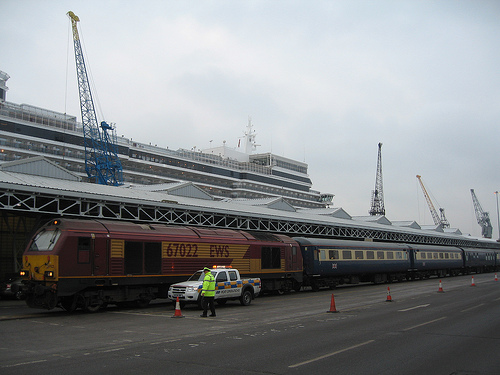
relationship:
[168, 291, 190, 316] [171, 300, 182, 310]
cone has stripe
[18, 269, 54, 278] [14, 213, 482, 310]
headlights on train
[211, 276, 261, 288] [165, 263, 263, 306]
checkers on truck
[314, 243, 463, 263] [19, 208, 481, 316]
stripe on train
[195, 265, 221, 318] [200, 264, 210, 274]
man wearing hat